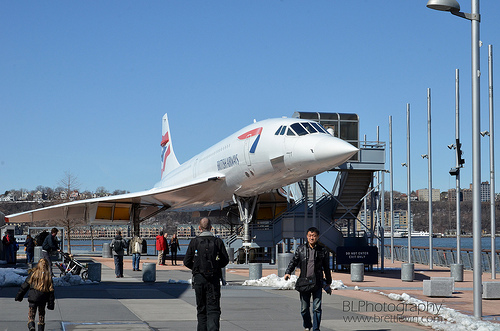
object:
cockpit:
[273, 118, 333, 139]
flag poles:
[425, 87, 433, 271]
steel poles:
[427, 87, 433, 271]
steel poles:
[454, 67, 461, 264]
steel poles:
[486, 43, 496, 279]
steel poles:
[387, 113, 395, 262]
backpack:
[192, 236, 219, 277]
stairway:
[297, 178, 318, 205]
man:
[180, 215, 229, 331]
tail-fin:
[158, 112, 181, 180]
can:
[86, 262, 102, 281]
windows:
[289, 122, 310, 137]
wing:
[5, 175, 222, 227]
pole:
[469, 0, 482, 318]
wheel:
[237, 248, 247, 265]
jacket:
[284, 242, 333, 288]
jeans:
[299, 280, 324, 331]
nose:
[317, 133, 363, 167]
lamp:
[425, 0, 479, 23]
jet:
[2, 111, 364, 225]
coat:
[183, 230, 229, 277]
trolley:
[53, 248, 88, 282]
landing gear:
[231, 193, 257, 264]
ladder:
[330, 162, 384, 220]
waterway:
[0, 236, 500, 275]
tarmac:
[0, 253, 500, 331]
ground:
[0, 252, 500, 331]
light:
[448, 169, 460, 176]